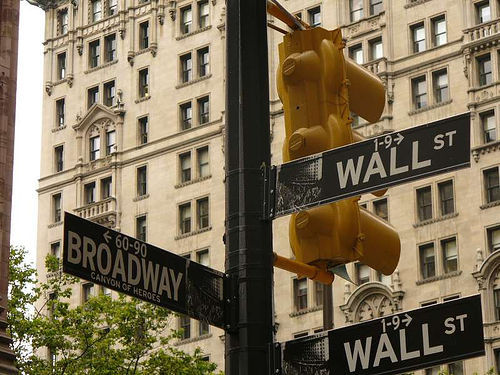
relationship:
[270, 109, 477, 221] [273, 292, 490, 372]
sign above sign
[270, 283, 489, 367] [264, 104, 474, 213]
street sign under street sign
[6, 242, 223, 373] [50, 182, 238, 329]
tree behind sign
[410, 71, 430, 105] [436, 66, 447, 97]
window next to window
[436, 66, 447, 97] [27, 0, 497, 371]
window on building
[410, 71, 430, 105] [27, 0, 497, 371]
window on building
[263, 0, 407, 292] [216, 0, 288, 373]
street signal on pole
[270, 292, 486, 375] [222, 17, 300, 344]
street sign on pole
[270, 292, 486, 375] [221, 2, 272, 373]
street sign on pole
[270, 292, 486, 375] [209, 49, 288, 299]
street sign on pole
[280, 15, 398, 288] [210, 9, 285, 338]
signal on pole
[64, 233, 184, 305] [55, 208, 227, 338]
lettering on sign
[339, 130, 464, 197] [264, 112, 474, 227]
lettering on sign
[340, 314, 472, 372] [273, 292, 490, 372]
lettering on sign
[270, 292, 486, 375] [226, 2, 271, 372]
street sign on pole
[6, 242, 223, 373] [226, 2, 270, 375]
tree growing near pole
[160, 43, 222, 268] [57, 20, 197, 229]
windows on side of building